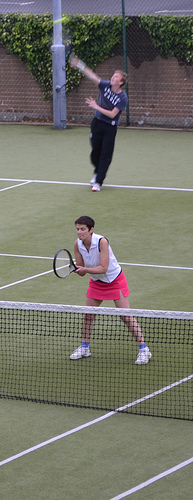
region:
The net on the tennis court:
[0, 301, 191, 420]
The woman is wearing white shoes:
[68, 347, 151, 363]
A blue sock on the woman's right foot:
[138, 343, 147, 348]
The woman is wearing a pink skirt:
[85, 273, 127, 298]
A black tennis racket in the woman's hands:
[53, 249, 79, 276]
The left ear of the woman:
[89, 227, 94, 233]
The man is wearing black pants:
[90, 118, 116, 183]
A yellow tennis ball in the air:
[55, 16, 65, 22]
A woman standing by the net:
[54, 215, 151, 363]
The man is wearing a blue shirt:
[93, 78, 126, 125]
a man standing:
[69, 52, 132, 204]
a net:
[4, 303, 68, 357]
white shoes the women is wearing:
[69, 346, 90, 358]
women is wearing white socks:
[137, 344, 148, 348]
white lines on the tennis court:
[133, 482, 144, 489]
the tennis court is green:
[3, 401, 38, 442]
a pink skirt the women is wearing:
[93, 282, 116, 299]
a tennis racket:
[51, 246, 81, 281]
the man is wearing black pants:
[91, 121, 113, 163]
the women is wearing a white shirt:
[83, 255, 98, 263]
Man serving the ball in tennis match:
[68, 54, 126, 190]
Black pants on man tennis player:
[87, 114, 116, 180]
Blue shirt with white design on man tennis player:
[91, 77, 123, 121]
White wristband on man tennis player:
[74, 59, 81, 67]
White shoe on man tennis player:
[89, 180, 97, 188]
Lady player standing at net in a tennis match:
[66, 212, 148, 361]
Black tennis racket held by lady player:
[50, 245, 72, 276]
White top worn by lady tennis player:
[74, 231, 118, 279]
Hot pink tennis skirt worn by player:
[84, 265, 129, 298]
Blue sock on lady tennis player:
[136, 342, 147, 349]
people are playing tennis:
[40, 31, 165, 374]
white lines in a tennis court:
[7, 372, 185, 492]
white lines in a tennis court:
[2, 171, 184, 225]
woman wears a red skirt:
[44, 214, 160, 375]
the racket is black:
[49, 247, 87, 281]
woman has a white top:
[64, 211, 129, 288]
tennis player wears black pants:
[60, 41, 132, 196]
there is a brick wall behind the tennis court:
[6, 11, 192, 138]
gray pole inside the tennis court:
[41, 1, 76, 130]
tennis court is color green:
[1, 126, 189, 496]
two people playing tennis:
[51, 19, 151, 366]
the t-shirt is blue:
[96, 81, 125, 124]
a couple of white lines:
[3, 422, 189, 497]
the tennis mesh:
[1, 302, 192, 420]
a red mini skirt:
[82, 271, 128, 299]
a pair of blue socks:
[81, 340, 144, 348]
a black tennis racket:
[45, 247, 79, 277]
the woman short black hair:
[74, 216, 95, 241]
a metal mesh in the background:
[133, 7, 192, 130]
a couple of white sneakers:
[68, 346, 152, 363]